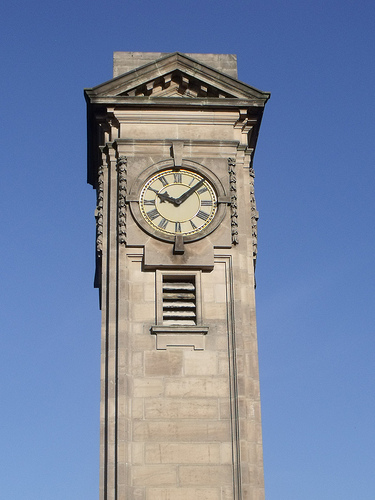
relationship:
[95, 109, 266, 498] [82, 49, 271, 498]
brickwork on brickwork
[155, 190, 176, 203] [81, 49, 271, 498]
hour hand on clock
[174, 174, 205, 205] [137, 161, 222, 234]
minute hand on clock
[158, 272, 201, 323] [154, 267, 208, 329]
shutters of a window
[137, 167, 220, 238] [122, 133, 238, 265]
face has four keystones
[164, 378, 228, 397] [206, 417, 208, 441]
stone have line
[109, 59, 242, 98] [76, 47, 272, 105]
triangles over roof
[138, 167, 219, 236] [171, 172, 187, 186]
clock face has numeral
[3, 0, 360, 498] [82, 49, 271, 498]
sky behind brickwork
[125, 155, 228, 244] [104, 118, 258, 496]
clock on wall